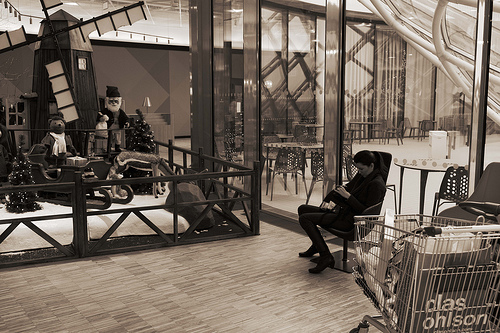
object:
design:
[167, 163, 287, 264]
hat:
[105, 85, 122, 99]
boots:
[308, 245, 336, 274]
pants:
[295, 205, 341, 264]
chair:
[344, 153, 399, 222]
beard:
[104, 97, 123, 113]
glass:
[258, 1, 477, 247]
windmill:
[0, 1, 153, 158]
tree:
[7, 139, 51, 220]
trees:
[117, 107, 165, 197]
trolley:
[344, 212, 500, 332]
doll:
[35, 115, 81, 167]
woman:
[297, 149, 389, 276]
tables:
[393, 154, 465, 230]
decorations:
[0, 1, 260, 264]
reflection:
[225, 16, 482, 93]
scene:
[0, 0, 500, 332]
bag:
[319, 184, 353, 215]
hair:
[352, 149, 391, 177]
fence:
[0, 133, 264, 270]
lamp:
[142, 95, 154, 115]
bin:
[424, 128, 458, 160]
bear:
[37, 116, 84, 169]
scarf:
[48, 132, 67, 156]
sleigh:
[19, 143, 135, 215]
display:
[0, 0, 259, 269]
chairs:
[264, 146, 311, 202]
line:
[204, 262, 222, 268]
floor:
[0, 208, 387, 332]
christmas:
[116, 108, 166, 197]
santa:
[95, 85, 131, 154]